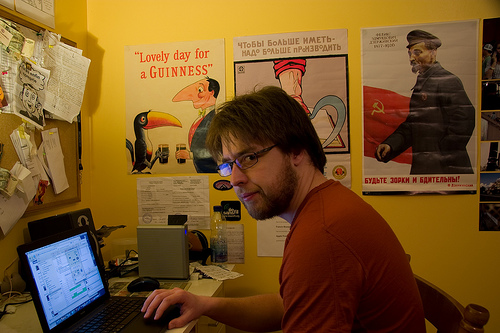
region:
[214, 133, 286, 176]
A pair of eye glasses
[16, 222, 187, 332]
A black lap top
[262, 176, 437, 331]
An orange tee shirt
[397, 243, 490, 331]
A wooden chair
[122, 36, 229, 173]
A colorful postal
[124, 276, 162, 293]
A black computer mouse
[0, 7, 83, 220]
A cork board with papers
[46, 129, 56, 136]
A yellow pin holding paper in place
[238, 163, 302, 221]
a beard on the mans chin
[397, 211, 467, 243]
A yellow wall in the background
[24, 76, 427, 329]
man sitting in front of laptop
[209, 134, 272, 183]
glasses on man's face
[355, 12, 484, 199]
poster on wall of Russian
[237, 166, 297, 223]
hair on man's face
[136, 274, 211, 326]
right hand on laptop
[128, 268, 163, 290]
computer mouse on pad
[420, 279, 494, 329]
back of wood chair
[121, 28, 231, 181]
poster with cartoon characters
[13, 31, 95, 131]
papers hanging on bulletin board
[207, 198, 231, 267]
water bottle on desk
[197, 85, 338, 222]
a boy is wearing glasses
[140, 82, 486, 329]
the man is sitting ina chair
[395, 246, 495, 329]
the chair is brown and wooden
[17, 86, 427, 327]
the man is working on a laptop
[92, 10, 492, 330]
the wall is painted yellow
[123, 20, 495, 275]
posters and papers are on the wall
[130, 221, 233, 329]
the modem is sitting on the desk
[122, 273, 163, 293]
a mouse is on the desk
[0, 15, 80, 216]
a bulletin board is on the wall in front of the man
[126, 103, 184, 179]
a toucan is on the poster next to the man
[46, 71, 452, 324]
man seated at a desk working on a computer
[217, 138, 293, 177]
a pair of eyeglasses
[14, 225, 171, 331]
laptop computer on a desk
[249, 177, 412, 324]
man is wearing a red t-shirt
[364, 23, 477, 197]
a poster on the wall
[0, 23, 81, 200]
a pegboard with many notes attached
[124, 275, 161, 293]
a black computer mouse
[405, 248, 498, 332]
the back of a chair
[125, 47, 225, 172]
a poster on a wall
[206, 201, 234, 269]
an empty beverage bottle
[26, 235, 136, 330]
computer monitor and keyboard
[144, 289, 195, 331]
man's fingers on keyboard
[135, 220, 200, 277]
gray router on table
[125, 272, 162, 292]
dark colored computer mouse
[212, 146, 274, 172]
man's eye and glasses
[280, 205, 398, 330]
man's orange tee shirt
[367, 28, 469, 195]
colorful poster on wall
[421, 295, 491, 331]
back of wooden chair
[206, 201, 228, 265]
clear bottle with blue top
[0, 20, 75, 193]
various pieces of paper on cork board